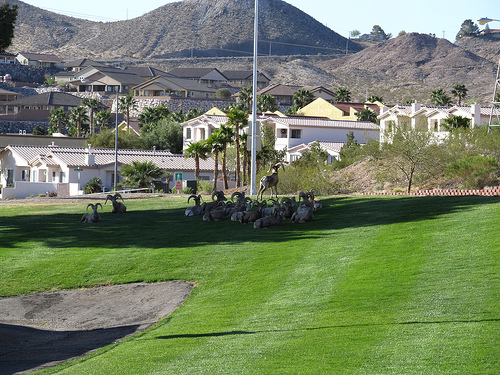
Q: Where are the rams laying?
A: In the shade.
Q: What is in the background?
A: A mountain.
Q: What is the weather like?
A: Sunny.